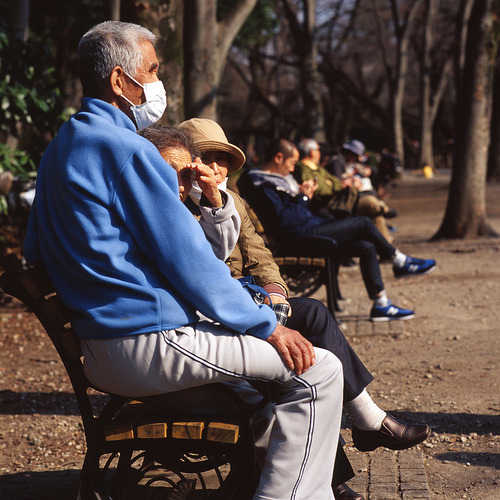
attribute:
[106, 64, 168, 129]
surgical mask — disposable, white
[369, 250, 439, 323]
shoes — blue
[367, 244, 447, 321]
shoes — blue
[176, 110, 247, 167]
hat — tan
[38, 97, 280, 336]
sweatshirt — blue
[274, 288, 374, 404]
pants — black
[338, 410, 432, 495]
shoes — brown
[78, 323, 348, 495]
sweatpants — white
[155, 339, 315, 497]
stripes — black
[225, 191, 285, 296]
jacket — brown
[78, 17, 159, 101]
hair — grey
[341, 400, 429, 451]
shoe — brown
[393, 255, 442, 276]
tennis shoe — blue, white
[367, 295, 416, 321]
tennis shoe — white, blue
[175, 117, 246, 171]
hat — tan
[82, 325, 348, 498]
pants — gray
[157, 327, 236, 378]
stripe — white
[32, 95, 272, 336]
shirt — light blue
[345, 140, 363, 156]
hat — grey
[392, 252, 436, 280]
shoe — blue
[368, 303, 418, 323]
shoe — blue